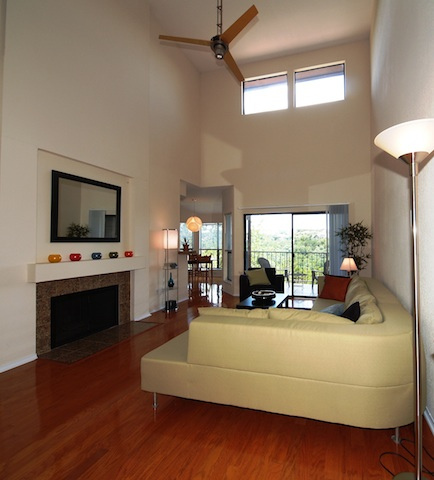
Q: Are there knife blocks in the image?
A: No, there are no knife blocks.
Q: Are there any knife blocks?
A: No, there are no knife blocks.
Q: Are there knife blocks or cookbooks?
A: No, there are no knife blocks or cookbooks.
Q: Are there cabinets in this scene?
A: No, there are no cabinets.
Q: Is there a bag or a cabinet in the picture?
A: No, there are no cabinets or bags.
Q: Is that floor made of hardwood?
A: Yes, the floor is made of hardwood.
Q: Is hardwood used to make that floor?
A: Yes, the floor is made of hardwood.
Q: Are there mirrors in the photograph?
A: Yes, there is a mirror.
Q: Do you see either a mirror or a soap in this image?
A: Yes, there is a mirror.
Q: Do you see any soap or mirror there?
A: Yes, there is a mirror.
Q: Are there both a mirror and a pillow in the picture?
A: Yes, there are both a mirror and a pillow.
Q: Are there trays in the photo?
A: No, there are no trays.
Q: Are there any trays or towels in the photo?
A: No, there are no trays or towels.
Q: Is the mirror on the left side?
A: Yes, the mirror is on the left of the image.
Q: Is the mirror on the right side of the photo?
A: No, the mirror is on the left of the image.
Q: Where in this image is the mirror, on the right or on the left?
A: The mirror is on the left of the image.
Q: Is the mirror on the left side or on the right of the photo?
A: The mirror is on the left of the image.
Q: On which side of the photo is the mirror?
A: The mirror is on the left of the image.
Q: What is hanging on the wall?
A: The mirror is hanging on the wall.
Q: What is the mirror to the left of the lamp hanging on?
A: The mirror is hanging on the wall.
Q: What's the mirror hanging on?
A: The mirror is hanging on the wall.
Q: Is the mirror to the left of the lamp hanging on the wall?
A: Yes, the mirror is hanging on the wall.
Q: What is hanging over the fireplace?
A: The mirror is hanging over the fireplace.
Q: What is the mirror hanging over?
A: The mirror is hanging over the fireplace.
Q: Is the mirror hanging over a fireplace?
A: Yes, the mirror is hanging over a fireplace.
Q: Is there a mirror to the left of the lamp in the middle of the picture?
A: Yes, there is a mirror to the left of the lamp.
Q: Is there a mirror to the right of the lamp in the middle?
A: No, the mirror is to the left of the lamp.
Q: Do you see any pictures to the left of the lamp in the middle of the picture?
A: No, there is a mirror to the left of the lamp.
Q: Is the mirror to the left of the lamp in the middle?
A: Yes, the mirror is to the left of the lamp.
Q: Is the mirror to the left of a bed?
A: No, the mirror is to the left of the lamp.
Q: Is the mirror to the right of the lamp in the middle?
A: No, the mirror is to the left of the lamp.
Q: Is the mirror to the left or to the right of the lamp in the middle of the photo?
A: The mirror is to the left of the lamp.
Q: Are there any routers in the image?
A: No, there are no routers.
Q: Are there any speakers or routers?
A: No, there are no routers or speakers.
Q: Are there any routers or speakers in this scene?
A: No, there are no routers or speakers.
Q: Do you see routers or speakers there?
A: No, there are no routers or speakers.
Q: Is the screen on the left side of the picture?
A: Yes, the screen is on the left of the image.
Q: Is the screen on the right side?
A: No, the screen is on the left of the image.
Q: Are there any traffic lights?
A: No, there are no traffic lights.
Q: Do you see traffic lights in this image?
A: No, there are no traffic lights.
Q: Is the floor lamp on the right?
A: Yes, the floor lamp is on the right of the image.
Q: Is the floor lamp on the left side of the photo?
A: No, the floor lamp is on the right of the image.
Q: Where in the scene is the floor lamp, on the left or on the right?
A: The floor lamp is on the right of the image.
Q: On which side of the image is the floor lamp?
A: The floor lamp is on the right of the image.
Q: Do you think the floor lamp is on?
A: Yes, the floor lamp is on.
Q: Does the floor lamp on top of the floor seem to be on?
A: Yes, the floor lamp is on.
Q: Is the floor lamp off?
A: No, the floor lamp is on.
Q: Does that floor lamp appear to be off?
A: No, the floor lamp is on.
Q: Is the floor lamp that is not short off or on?
A: The floor lamp is on.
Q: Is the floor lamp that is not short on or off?
A: The floor lamp is on.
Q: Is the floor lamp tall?
A: Yes, the floor lamp is tall.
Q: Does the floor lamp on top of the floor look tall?
A: Yes, the floor lamp is tall.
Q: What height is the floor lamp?
A: The floor lamp is tall.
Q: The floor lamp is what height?
A: The floor lamp is tall.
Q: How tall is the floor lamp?
A: The floor lamp is tall.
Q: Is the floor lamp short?
A: No, the floor lamp is tall.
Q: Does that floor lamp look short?
A: No, the floor lamp is tall.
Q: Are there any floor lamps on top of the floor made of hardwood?
A: Yes, there is a floor lamp on top of the floor.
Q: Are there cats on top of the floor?
A: No, there is a floor lamp on top of the floor.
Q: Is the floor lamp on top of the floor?
A: Yes, the floor lamp is on top of the floor.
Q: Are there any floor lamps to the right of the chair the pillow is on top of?
A: Yes, there is a floor lamp to the right of the chair.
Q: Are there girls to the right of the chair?
A: No, there is a floor lamp to the right of the chair.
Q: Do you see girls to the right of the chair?
A: No, there is a floor lamp to the right of the chair.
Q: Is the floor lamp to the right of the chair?
A: Yes, the floor lamp is to the right of the chair.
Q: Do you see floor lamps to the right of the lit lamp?
A: Yes, there is a floor lamp to the right of the lamp.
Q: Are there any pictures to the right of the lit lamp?
A: No, there is a floor lamp to the right of the lamp.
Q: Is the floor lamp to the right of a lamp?
A: Yes, the floor lamp is to the right of a lamp.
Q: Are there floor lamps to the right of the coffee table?
A: Yes, there is a floor lamp to the right of the coffee table.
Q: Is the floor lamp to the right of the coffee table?
A: Yes, the floor lamp is to the right of the coffee table.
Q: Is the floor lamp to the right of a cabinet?
A: No, the floor lamp is to the right of the coffee table.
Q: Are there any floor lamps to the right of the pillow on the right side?
A: Yes, there is a floor lamp to the right of the pillow.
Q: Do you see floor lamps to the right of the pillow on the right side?
A: Yes, there is a floor lamp to the right of the pillow.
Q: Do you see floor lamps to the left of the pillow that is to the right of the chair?
A: No, the floor lamp is to the right of the pillow.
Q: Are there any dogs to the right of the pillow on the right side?
A: No, there is a floor lamp to the right of the pillow.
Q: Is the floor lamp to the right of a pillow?
A: Yes, the floor lamp is to the right of a pillow.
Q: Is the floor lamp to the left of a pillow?
A: No, the floor lamp is to the right of a pillow.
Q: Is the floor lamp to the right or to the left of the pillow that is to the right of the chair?
A: The floor lamp is to the right of the pillow.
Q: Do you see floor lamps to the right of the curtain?
A: Yes, there is a floor lamp to the right of the curtain.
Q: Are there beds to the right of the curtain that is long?
A: No, there is a floor lamp to the right of the curtain.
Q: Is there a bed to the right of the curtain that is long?
A: No, there is a floor lamp to the right of the curtain.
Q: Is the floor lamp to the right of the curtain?
A: Yes, the floor lamp is to the right of the curtain.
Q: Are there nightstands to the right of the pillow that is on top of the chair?
A: No, there is a floor lamp to the right of the pillow.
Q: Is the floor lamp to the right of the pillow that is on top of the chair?
A: Yes, the floor lamp is to the right of the pillow.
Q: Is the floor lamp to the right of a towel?
A: No, the floor lamp is to the right of the pillow.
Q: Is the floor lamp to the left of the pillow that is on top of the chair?
A: No, the floor lamp is to the right of the pillow.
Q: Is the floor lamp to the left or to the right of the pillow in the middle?
A: The floor lamp is to the right of the pillow.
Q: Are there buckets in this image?
A: No, there are no buckets.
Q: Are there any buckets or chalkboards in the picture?
A: No, there are no buckets or chalkboards.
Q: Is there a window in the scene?
A: Yes, there is a window.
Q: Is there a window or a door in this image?
A: Yes, there is a window.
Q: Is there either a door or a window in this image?
A: Yes, there is a window.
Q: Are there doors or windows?
A: Yes, there is a window.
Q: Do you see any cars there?
A: No, there are no cars.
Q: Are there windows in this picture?
A: Yes, there is a window.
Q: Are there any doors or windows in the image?
A: Yes, there is a window.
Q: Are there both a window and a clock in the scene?
A: No, there is a window but no clocks.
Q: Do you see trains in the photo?
A: No, there are no trains.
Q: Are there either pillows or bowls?
A: Yes, there is a pillow.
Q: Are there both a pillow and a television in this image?
A: No, there is a pillow but no televisions.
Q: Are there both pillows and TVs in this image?
A: No, there is a pillow but no televisions.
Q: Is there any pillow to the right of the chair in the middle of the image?
A: Yes, there is a pillow to the right of the chair.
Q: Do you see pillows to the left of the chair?
A: No, the pillow is to the right of the chair.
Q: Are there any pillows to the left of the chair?
A: No, the pillow is to the right of the chair.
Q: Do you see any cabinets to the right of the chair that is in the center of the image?
A: No, there is a pillow to the right of the chair.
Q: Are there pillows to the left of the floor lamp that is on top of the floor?
A: Yes, there is a pillow to the left of the floor lamp.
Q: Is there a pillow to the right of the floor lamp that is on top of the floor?
A: No, the pillow is to the left of the floor lamp.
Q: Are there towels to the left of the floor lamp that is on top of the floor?
A: No, there is a pillow to the left of the floor lamp.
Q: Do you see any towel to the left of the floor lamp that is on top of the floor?
A: No, there is a pillow to the left of the floor lamp.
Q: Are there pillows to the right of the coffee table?
A: Yes, there is a pillow to the right of the coffee table.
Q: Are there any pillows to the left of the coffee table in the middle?
A: No, the pillow is to the right of the coffee table.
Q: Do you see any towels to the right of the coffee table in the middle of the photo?
A: No, there is a pillow to the right of the coffee table.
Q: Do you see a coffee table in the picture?
A: Yes, there is a coffee table.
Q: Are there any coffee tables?
A: Yes, there is a coffee table.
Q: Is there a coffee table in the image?
A: Yes, there is a coffee table.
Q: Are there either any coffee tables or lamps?
A: Yes, there is a coffee table.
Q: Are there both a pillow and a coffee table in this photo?
A: Yes, there are both a coffee table and a pillow.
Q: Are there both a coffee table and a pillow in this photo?
A: Yes, there are both a coffee table and a pillow.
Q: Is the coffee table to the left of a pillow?
A: Yes, the coffee table is to the left of a pillow.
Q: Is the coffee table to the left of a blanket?
A: No, the coffee table is to the left of a pillow.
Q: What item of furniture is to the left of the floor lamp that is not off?
A: The piece of furniture is a coffee table.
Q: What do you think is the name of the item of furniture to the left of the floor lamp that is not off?
A: The piece of furniture is a coffee table.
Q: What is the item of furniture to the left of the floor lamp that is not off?
A: The piece of furniture is a coffee table.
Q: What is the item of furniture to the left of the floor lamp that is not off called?
A: The piece of furniture is a coffee table.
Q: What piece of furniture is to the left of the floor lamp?
A: The piece of furniture is a coffee table.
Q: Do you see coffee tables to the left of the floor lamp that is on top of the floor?
A: Yes, there is a coffee table to the left of the floor lamp.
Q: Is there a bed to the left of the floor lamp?
A: No, there is a coffee table to the left of the floor lamp.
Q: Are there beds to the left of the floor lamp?
A: No, there is a coffee table to the left of the floor lamp.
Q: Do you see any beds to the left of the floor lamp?
A: No, there is a coffee table to the left of the floor lamp.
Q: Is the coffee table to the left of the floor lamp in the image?
A: Yes, the coffee table is to the left of the floor lamp.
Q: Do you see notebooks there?
A: No, there are no notebooks.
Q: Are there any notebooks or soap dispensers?
A: No, there are no notebooks or soap dispensers.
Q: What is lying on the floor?
A: The wire is lying on the floor.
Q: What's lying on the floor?
A: The wire is lying on the floor.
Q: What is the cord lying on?
A: The cord is lying on the floor.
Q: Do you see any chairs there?
A: Yes, there is a chair.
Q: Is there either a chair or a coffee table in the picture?
A: Yes, there is a chair.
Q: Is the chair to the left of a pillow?
A: Yes, the chair is to the left of a pillow.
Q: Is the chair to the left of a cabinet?
A: No, the chair is to the left of a pillow.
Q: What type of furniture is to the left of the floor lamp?
A: The piece of furniture is a chair.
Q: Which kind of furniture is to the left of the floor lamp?
A: The piece of furniture is a chair.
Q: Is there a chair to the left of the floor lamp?
A: Yes, there is a chair to the left of the floor lamp.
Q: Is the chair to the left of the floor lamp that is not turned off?
A: Yes, the chair is to the left of the floor lamp.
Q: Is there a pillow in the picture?
A: Yes, there is a pillow.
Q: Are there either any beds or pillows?
A: Yes, there is a pillow.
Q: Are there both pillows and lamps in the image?
A: Yes, there are both a pillow and a lamp.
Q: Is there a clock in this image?
A: No, there are no clocks.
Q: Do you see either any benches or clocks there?
A: No, there are no clocks or benches.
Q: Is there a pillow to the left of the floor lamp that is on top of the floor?
A: Yes, there is a pillow to the left of the floor lamp.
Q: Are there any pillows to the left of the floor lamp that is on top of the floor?
A: Yes, there is a pillow to the left of the floor lamp.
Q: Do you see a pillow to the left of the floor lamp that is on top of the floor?
A: Yes, there is a pillow to the left of the floor lamp.